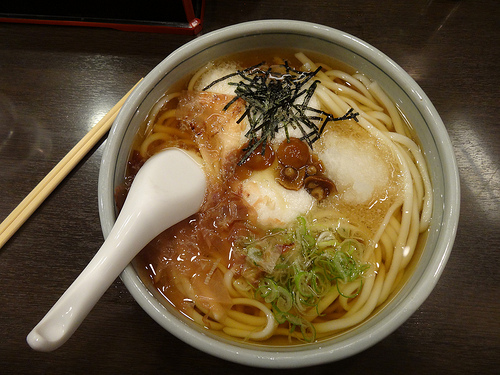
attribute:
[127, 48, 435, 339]
food — soup, brown, ramen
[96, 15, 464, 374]
bowl — white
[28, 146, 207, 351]
spoon — ceramic, chinese, white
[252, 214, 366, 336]
onions — green, vegetables, vegetable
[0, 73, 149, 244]
chopsticks — chinese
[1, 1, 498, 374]
table — wood, shiny, brown, wooden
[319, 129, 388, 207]
cream — white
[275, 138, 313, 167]
mushroom — brown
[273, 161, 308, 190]
mushroom — brown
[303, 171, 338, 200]
mushroom — brown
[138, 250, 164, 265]
broth — brown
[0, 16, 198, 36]
edge — red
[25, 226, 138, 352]
handle — white